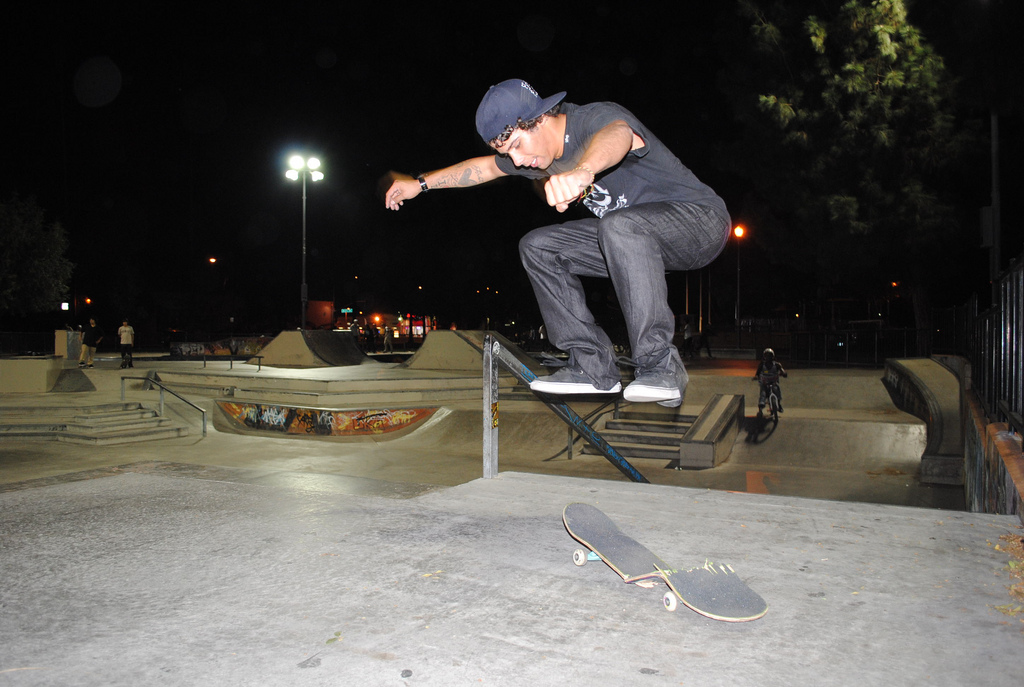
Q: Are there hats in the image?
A: Yes, there is a hat.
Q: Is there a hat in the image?
A: Yes, there is a hat.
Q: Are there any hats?
A: Yes, there is a hat.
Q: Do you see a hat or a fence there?
A: Yes, there is a hat.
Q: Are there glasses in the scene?
A: No, there are no glasses.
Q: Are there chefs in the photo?
A: No, there are no chefs.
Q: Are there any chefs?
A: No, there are no chefs.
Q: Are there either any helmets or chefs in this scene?
A: No, there are no chefs or helmets.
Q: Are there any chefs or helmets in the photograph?
A: No, there are no chefs or helmets.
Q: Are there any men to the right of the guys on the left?
A: Yes, there is a man to the right of the guys.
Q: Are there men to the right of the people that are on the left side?
A: Yes, there is a man to the right of the guys.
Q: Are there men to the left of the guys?
A: No, the man is to the right of the guys.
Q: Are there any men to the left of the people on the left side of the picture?
A: No, the man is to the right of the guys.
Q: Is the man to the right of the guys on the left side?
A: Yes, the man is to the right of the guys.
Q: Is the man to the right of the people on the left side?
A: Yes, the man is to the right of the guys.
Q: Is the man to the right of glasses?
A: No, the man is to the right of the guys.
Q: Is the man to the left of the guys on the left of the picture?
A: No, the man is to the right of the guys.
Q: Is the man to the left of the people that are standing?
A: No, the man is to the right of the guys.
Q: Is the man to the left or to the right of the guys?
A: The man is to the right of the guys.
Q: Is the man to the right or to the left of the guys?
A: The man is to the right of the guys.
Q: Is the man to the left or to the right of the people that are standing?
A: The man is to the right of the guys.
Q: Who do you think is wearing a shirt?
A: The man is wearing a shirt.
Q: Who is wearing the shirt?
A: The man is wearing a shirt.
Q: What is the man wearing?
A: The man is wearing a shirt.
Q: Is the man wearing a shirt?
A: Yes, the man is wearing a shirt.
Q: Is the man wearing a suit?
A: No, the man is wearing a shirt.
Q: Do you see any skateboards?
A: Yes, there is a skateboard.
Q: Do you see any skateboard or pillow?
A: Yes, there is a skateboard.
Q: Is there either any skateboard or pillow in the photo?
A: Yes, there is a skateboard.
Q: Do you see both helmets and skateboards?
A: No, there is a skateboard but no helmets.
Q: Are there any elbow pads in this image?
A: No, there are no elbow pads.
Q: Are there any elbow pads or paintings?
A: No, there are no elbow pads or paintings.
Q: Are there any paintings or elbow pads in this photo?
A: No, there are no elbow pads or paintings.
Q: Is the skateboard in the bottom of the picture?
A: Yes, the skateboard is in the bottom of the image.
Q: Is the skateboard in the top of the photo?
A: No, the skateboard is in the bottom of the image.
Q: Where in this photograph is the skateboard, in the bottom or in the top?
A: The skateboard is in the bottom of the image.